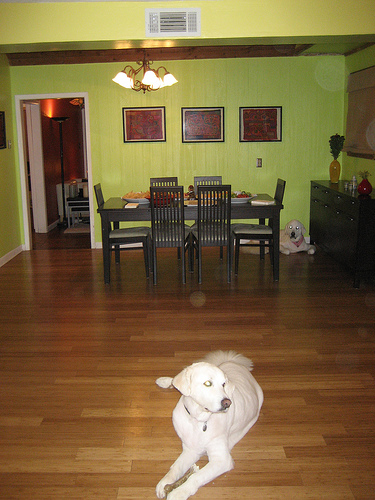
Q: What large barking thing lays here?
A: Dog.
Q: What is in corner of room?
A: Dog.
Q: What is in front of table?
A: Dog.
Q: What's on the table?
A: Food.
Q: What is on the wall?
A: Pictures.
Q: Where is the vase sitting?
A: On hutch.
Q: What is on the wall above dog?
A: Vent.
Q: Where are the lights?
A: Ceiling.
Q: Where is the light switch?
A: On wall.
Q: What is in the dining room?
A: Table and chairs.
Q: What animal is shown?
A: Dogs.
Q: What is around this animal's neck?
A: Collar.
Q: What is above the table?
A: Dining room light.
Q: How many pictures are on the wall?
A: Three.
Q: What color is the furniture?
A: Black.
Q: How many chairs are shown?
A: Six.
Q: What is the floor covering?
A: Wood.